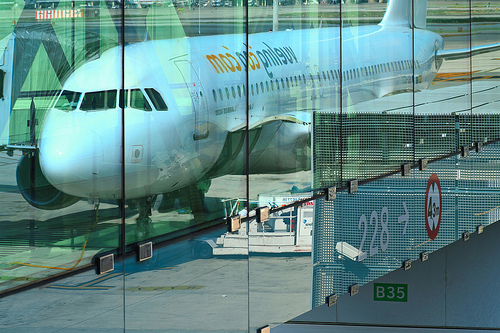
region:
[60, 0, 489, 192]
white airplane on runway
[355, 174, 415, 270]
228 is written in white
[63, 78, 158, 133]
dark windows on airplane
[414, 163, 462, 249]
sign is red and white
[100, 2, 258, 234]
large windows near airplane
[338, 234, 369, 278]
white camera on wall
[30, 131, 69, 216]
engine on airplane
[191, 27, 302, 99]
orange and grey logo on plane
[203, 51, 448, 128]
row of windows on plane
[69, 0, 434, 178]
large white plane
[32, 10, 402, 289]
the plane is white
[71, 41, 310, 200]
the plane is white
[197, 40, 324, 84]
Yellow and gray writing on plane.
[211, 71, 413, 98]
Many windows a long side of plane.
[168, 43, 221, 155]
White door on side of plane near front.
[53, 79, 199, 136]
Large clear windshield at front of plane.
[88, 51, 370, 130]
Plane is mostly white in color.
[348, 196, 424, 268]
White writing on glass.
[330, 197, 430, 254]
White writing says 228.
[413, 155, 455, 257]
Red circle on glass.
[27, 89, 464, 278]
Large windows looking outside.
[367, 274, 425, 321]
B35 written in green box.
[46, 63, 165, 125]
Cockpit windows on an airplane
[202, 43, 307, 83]
Name of the airlines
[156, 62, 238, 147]
door to load passengers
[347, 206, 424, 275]
sign that points to gate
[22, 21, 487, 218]
Big white airplane on the tarmack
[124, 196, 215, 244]
wheel to a large plane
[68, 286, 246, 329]
tarmac for an airport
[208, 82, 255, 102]
Windows on the left side of plane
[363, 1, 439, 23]
The tail of the plane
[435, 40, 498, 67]
A wing on the plane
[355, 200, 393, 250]
White number 228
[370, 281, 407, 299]
White B35 on green background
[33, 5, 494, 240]
Parked white passenger plane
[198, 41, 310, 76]
Airline name on left side of plane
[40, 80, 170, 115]
Windshield of cockpit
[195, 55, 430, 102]
Passenger windows on left side of plane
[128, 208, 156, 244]
Front wheel of airplane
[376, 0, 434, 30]
Vertical stabilizer at back of plane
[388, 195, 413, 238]
White arrow on aqua colored background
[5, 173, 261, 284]
Ground plane is sitting on